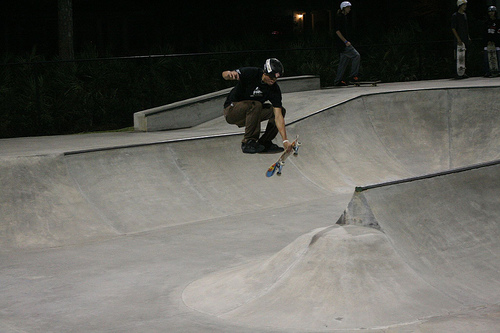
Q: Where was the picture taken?
A: At a skate park.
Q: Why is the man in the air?
A: He is performing a skateboard trick.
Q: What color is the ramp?
A: Grey.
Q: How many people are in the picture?
A: Four.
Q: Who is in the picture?
A: Skateboarders.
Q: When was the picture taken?
A: At night.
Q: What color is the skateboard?
A: Blue.